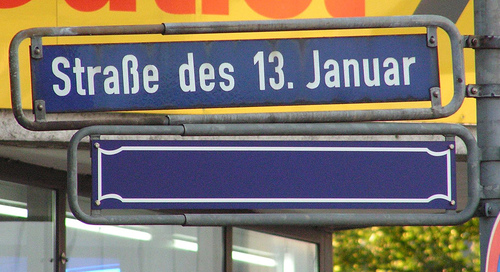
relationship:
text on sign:
[52, 50, 415, 97] [30, 33, 440, 110]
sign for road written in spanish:
[1, 18, 451, 108] [34, 50, 416, 111]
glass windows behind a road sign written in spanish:
[0, 174, 57, 271] [36, 100, 426, 124]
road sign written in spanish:
[19, 100, 98, 217] [50, 50, 420, 91]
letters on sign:
[307, 46, 412, 90] [16, 33, 449, 104]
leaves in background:
[327, 214, 479, 271] [316, 223, 474, 269]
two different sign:
[45, 74, 480, 214] [27, 32, 429, 103]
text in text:
[52, 50, 415, 97] [52, 50, 415, 97]